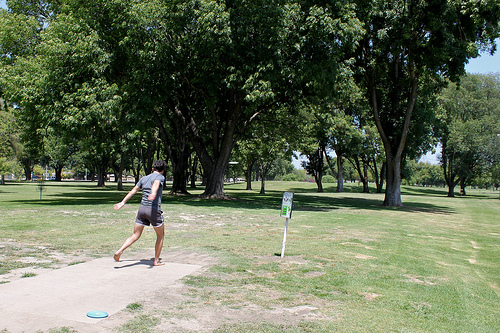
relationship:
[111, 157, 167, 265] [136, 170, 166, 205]
man wearing t shirt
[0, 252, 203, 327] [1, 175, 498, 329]
mat on grass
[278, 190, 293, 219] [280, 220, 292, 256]
sign on post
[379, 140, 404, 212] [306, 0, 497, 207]
trunk on tree